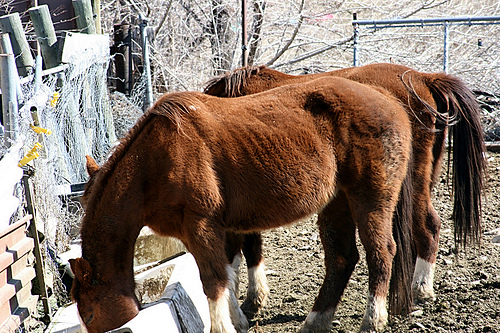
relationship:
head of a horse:
[72, 270, 140, 332] [48, 75, 408, 331]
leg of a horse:
[178, 210, 238, 331] [48, 75, 408, 331]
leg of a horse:
[294, 190, 361, 331] [48, 75, 408, 331]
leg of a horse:
[231, 223, 276, 327] [48, 75, 408, 331]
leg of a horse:
[403, 165, 448, 316] [48, 75, 408, 331]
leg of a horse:
[240, 233, 269, 298] [165, 55, 495, 317]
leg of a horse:
[240, 233, 269, 298] [200, 63, 487, 320]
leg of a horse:
[408, 140, 443, 292] [195, 64, 483, 294]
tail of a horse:
[385, 146, 420, 313] [48, 75, 408, 331]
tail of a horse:
[385, 146, 420, 313] [197, 56, 473, 306]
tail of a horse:
[424, 68, 493, 258] [163, 59, 475, 331]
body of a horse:
[186, 102, 378, 197] [179, 94, 381, 193]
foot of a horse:
[192, 272, 229, 333] [66, 88, 398, 331]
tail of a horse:
[427, 74, 492, 258] [254, 147, 389, 221]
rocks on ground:
[260, 257, 321, 304] [400, 283, 461, 329]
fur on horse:
[105, 98, 165, 234] [124, 127, 392, 214]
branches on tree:
[139, 53, 199, 113] [162, 15, 334, 78]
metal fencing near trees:
[359, 17, 496, 34] [145, 0, 499, 73]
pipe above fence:
[29, 0, 44, 103] [0, 52, 118, 316]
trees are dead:
[101, 0, 449, 75] [132, 50, 193, 95]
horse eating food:
[48, 75, 408, 331] [137, 268, 164, 309]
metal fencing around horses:
[351, 12, 499, 150] [63, 65, 484, 325]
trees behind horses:
[101, 0, 358, 69] [63, 65, 484, 325]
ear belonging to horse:
[60, 250, 106, 292] [48, 75, 408, 331]